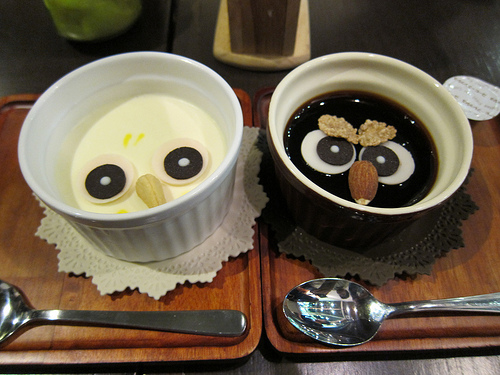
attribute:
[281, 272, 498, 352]
spoon — silver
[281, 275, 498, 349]
utensil — is silver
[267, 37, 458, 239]
bowl — is full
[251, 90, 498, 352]
tray — is wooden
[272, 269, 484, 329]
spoon — is silver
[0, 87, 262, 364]
tray — brown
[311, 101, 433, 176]
bowl — is full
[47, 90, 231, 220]
cream — white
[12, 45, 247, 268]
cup — white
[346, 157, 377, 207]
almond — is edible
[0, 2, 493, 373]
table — is high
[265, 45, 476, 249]
bowl — brown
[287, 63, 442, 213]
dessert — is cute, is high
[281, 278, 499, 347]
spoon — silver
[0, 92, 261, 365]
plates — brown, wooden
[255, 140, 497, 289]
paper — black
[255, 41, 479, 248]
cup — black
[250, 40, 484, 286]
cloth — black